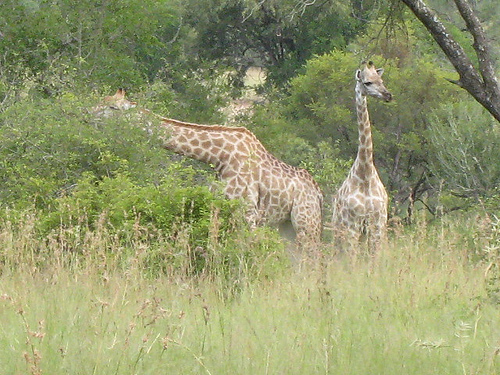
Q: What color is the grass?
A: Green.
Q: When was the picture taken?
A: During the day.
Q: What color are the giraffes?
A: Brown.